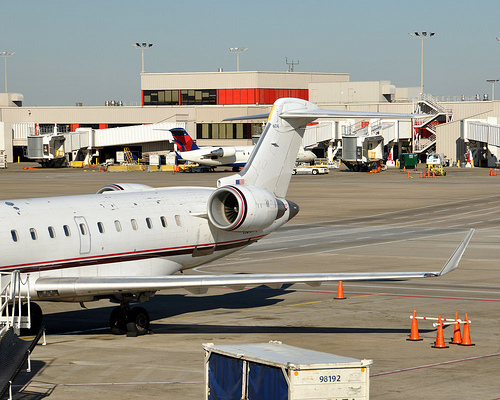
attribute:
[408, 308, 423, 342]
cone — orange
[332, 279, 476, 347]
cones — safety, orange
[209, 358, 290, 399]
luggage — held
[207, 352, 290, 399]
curtain — blue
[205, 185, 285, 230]
engine — white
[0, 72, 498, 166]
building — white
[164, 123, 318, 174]
plane — another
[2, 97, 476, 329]
planes — sitting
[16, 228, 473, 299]
wing — long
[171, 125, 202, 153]
tail — colorful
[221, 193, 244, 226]
turbine — silver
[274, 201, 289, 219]
tip — grey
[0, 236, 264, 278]
line — red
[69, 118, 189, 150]
walkway — white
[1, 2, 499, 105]
sky — blue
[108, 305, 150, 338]
wheels — black